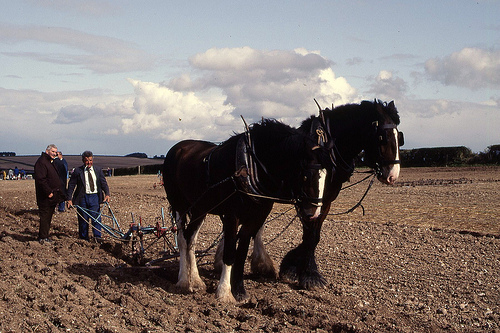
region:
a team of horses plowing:
[110, 76, 426, 313]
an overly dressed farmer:
[59, 92, 410, 307]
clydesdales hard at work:
[156, 89, 409, 309]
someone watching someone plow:
[30, 131, 122, 256]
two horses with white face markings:
[138, 88, 426, 309]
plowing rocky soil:
[0, 231, 498, 331]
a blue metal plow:
[0, 98, 497, 325]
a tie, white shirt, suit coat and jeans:
[65, 146, 112, 239]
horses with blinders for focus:
[154, 86, 417, 308]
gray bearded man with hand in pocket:
[0, 126, 68, 243]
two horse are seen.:
[168, 126, 400, 249]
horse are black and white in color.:
[168, 138, 415, 304]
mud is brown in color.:
[22, 241, 161, 328]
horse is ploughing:
[82, 194, 231, 284]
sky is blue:
[64, 11, 212, 41]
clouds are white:
[109, 78, 264, 121]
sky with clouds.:
[60, 36, 224, 103]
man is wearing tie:
[84, 167, 99, 184]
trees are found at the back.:
[418, 143, 491, 171]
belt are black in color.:
[231, 108, 393, 230]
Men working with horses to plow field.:
[32, 94, 405, 306]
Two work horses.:
[162, 99, 407, 301]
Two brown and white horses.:
[159, 99, 404, 297]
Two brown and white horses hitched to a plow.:
[67, 98, 404, 305]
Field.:
[0, 166, 498, 331]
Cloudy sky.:
[2, 32, 498, 154]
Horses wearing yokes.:
[157, 96, 403, 306]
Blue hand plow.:
[63, 194, 180, 267]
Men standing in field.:
[30, 142, 112, 242]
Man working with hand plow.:
[69, 150, 179, 267]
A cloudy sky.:
[11, 20, 311, 121]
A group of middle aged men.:
[22, 130, 107, 247]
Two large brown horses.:
[145, 95, 410, 305]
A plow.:
[65, 187, 175, 277]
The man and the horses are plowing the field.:
[70, 55, 405, 305]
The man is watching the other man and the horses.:
[25, 130, 70, 235]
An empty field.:
[395, 50, 490, 315]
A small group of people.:
[0, 155, 25, 185]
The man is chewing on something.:
[70, 140, 100, 235]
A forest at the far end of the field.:
[410, 130, 495, 190]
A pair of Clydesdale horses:
[158, 91, 418, 316]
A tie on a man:
[86, 166, 97, 194]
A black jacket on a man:
[33, 148, 72, 210]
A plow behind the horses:
[71, 196, 199, 273]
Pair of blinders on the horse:
[371, 126, 406, 150]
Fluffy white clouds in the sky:
[104, 36, 364, 141]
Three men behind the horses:
[28, 141, 110, 243]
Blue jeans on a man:
[75, 191, 104, 243]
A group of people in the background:
[0, 161, 31, 180]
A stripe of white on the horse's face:
[312, 162, 329, 219]